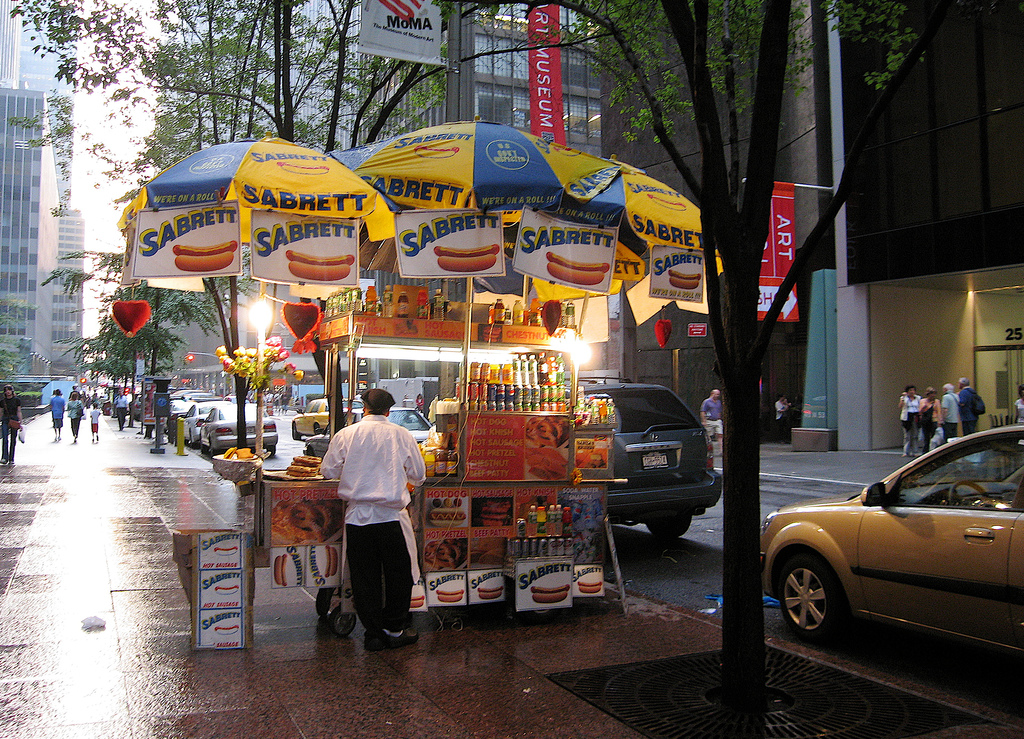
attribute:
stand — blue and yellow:
[95, 87, 789, 673]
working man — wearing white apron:
[296, 368, 439, 662]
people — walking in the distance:
[11, 312, 143, 472]